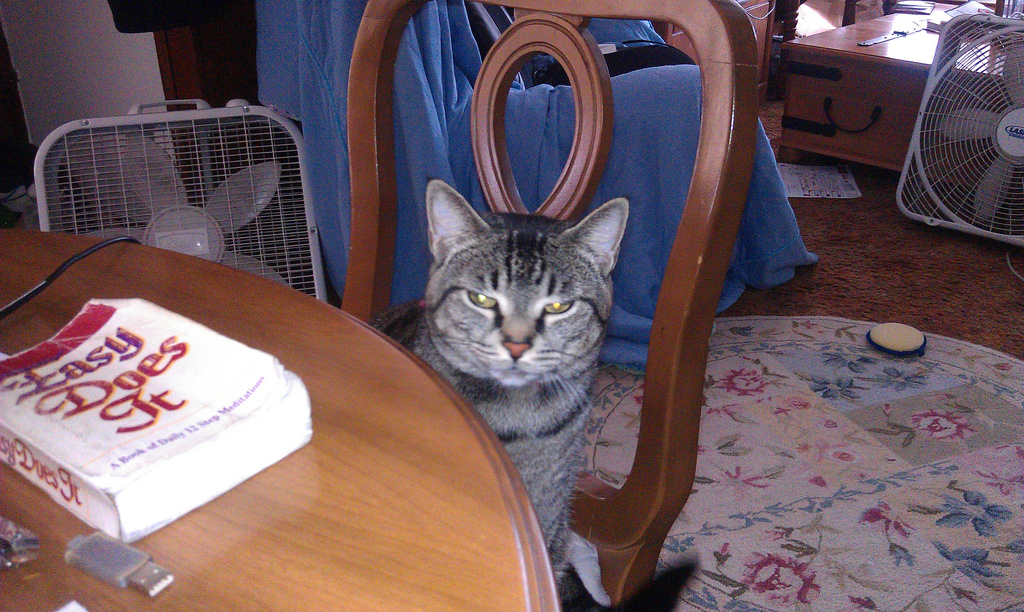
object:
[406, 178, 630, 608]
cat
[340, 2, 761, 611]
chair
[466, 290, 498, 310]
eye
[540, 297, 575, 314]
eye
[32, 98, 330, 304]
box fan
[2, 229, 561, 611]
table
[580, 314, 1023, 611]
rug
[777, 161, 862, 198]
paper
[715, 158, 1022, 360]
floor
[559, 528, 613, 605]
tail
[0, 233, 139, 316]
cord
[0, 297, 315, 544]
book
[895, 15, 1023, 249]
fan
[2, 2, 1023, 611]
room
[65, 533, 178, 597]
usb drive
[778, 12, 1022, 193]
chest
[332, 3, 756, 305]
chair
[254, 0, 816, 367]
blanket